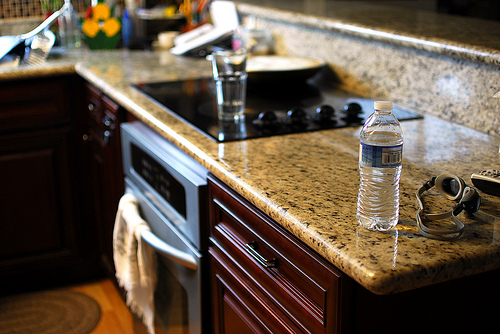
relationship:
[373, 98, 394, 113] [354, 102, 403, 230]
cap on bottle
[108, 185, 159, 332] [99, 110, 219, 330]
towel hanging on door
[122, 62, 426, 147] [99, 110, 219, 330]
stove has door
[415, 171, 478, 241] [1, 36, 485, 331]
goggles on counter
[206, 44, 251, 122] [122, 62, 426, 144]
glass on stove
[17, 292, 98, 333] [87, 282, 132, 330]
rug on floor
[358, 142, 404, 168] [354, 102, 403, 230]
label on bottle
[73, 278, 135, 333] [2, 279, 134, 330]
wood on floor